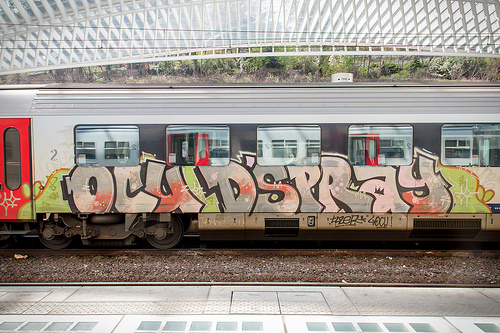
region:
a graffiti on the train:
[71, 163, 453, 250]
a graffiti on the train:
[42, 151, 427, 216]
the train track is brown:
[107, 249, 387, 284]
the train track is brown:
[105, 205, 347, 296]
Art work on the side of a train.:
[6, 145, 499, 231]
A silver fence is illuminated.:
[1, 0, 498, 67]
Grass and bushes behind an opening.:
[66, 44, 495, 81]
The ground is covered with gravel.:
[0, 253, 499, 284]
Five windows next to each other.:
[73, 124, 497, 166]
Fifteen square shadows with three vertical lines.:
[2, 315, 499, 331]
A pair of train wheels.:
[38, 212, 184, 251]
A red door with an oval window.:
[1, 116, 34, 226]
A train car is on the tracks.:
[0, 82, 496, 255]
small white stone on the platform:
[6, 251, 33, 266]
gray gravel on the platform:
[212, 257, 277, 262]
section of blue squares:
[35, 314, 135, 331]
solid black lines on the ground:
[95, 272, 337, 290]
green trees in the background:
[170, 49, 362, 73]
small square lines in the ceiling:
[43, 17, 207, 44]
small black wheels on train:
[135, 215, 191, 251]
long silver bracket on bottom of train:
[192, 207, 425, 239]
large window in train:
[161, 117, 243, 180]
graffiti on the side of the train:
[147, 169, 322, 201]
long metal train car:
[4, 80, 495, 254]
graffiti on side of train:
[8, 155, 498, 218]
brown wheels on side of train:
[26, 215, 190, 266]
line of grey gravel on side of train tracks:
[1, 257, 497, 280]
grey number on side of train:
[43, 145, 61, 162]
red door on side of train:
[4, 115, 43, 220]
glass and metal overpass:
[3, 3, 498, 79]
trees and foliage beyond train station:
[64, 51, 478, 79]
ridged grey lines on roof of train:
[26, 87, 497, 117]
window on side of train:
[65, 113, 149, 168]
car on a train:
[33, 98, 493, 208]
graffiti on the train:
[68, 160, 483, 212]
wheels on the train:
[41, 215, 187, 246]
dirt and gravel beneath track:
[108, 262, 263, 277]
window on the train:
[348, 126, 412, 166]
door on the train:
[2, 123, 33, 215]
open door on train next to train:
[166, 133, 216, 164]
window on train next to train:
[271, 140, 300, 159]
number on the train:
[44, 148, 65, 163]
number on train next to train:
[404, 141, 416, 153]